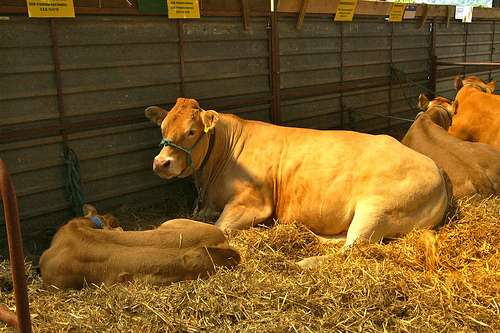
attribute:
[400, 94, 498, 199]
cow — tied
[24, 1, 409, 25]
signs — yellow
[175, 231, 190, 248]
straw — yellow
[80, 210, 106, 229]
collar — blue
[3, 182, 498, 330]
straw — yellow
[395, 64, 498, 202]
cow — tied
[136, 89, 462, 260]
cow — lying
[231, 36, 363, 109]
fencing — metal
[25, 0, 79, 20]
sign — laminated, white, green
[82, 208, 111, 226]
collar — blue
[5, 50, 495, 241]
wall — long, metal